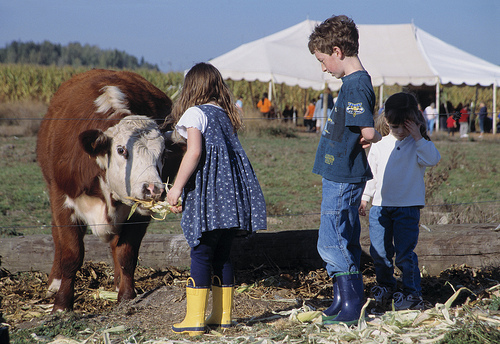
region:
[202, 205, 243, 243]
edge of a dress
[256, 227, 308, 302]
part of a shade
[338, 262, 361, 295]
edge of a boot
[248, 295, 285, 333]
part of a ground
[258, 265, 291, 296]
part of a grounmd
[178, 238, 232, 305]
part of a jeans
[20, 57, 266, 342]
A little girl feeding a cow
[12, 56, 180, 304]
a large brown and white cow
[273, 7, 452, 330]
two boys stand behind the girl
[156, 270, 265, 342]
Yellow and blue boots on girl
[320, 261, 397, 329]
Blue and green boots on boy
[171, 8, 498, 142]
A large white canopy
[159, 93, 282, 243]
Blue and white dress on gril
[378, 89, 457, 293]
Little boy with hand to his head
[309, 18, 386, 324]
Boy with arms behind his back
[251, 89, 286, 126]
person wearing and orange shirt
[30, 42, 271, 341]
a little girl giving food to a cow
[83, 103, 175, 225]
head of cow is white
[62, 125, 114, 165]
ear of cow is brown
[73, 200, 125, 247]
chest of cow id white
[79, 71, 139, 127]
a white spot on brown body of cow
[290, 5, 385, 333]
a boy wearing blue boots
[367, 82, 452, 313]
a toddler comb with a pony tail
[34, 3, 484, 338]
kids are in a farm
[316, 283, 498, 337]
corn husks on a pile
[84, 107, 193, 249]
cow is eating corn husks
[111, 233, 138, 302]
leg of red cow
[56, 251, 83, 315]
leg of red cow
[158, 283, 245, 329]
yellow rubber boots on kid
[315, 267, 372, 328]
blue rubber boots on kid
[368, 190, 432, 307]
blue jeans on kid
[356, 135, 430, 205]
white shirt on kid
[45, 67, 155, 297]
red cow with white face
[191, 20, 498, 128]
white tent in background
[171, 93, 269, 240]
floral dress on little girl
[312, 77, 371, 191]
navy blue tshirt on boy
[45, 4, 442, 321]
kids feeding a cow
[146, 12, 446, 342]
the kdis has on boots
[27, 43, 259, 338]
the girl feeds the cow some corn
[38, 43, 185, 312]
the cow is brown and white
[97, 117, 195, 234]
the cow has a white face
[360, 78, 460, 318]
this child is covering their face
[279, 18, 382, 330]
this boy has on a blue shirt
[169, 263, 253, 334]
the girl's boots are yellow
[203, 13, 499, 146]
there is a tent in the background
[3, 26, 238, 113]
there is a treeline in the fair area